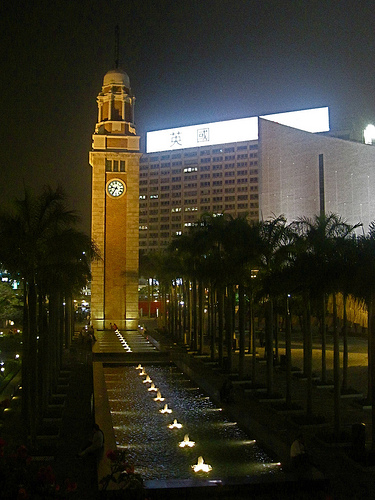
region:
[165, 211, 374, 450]
row of trees on right side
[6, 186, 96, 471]
row of trees on left side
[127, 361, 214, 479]
foreground row of lit candles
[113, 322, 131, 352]
background row of lit candles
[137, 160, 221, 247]
window with lights on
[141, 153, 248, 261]
rows of windows on side of building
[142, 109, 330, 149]
lighted billboard on top of building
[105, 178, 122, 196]
white clock face with black number markings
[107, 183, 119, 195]
big hand and little hand on clock face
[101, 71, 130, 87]
dome on top of clock tower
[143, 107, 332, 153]
light up board on top of building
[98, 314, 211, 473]
line of lit candles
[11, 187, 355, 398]
trees lining both sides of candles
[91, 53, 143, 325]
clock tower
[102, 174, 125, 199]
white clock face on clock tower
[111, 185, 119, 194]
black little and big hand of clock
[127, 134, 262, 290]
building that large lighted sign is on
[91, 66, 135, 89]
domed top of clock tower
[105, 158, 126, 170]
windows on clock tower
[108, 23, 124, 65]
black pole on top of clock tower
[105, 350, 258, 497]
light in the pool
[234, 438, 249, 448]
glow of the light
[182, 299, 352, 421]
tree trucks next to the pool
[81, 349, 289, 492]
water in the pool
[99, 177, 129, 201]
clock on the building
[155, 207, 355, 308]
tree tops in front of the building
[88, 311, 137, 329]
lights glow on the building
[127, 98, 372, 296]
building behind the pool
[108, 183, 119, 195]
hands on the clock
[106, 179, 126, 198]
face of the clock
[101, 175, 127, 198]
a clock in the center of the building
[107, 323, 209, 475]
lights in the center of the water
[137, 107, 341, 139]
a large sign on the top of the building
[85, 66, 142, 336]
a tall narrow tower with a clock in the middle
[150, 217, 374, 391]
a row of tall trees next to the water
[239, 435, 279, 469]
lights on the side of the water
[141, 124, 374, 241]
a tall building with many windows on the side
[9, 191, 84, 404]
more trees to the left of the water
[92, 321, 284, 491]
two pools of water in front of the tower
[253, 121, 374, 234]
the wall on the side of the building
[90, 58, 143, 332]
Hong Kong clock tower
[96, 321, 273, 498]
lighted pools before the tower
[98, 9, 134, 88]
lightening rod mounted on dome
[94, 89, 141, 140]
the belfry on the clock tower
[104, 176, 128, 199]
white face of clock with black hands and numbers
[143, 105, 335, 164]
large digital sign on top of hotel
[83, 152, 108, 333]
corners of tower are granite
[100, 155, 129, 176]
three windows side by side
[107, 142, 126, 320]
center of walls are made of brick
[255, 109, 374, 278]
the Hong Kong cultural center